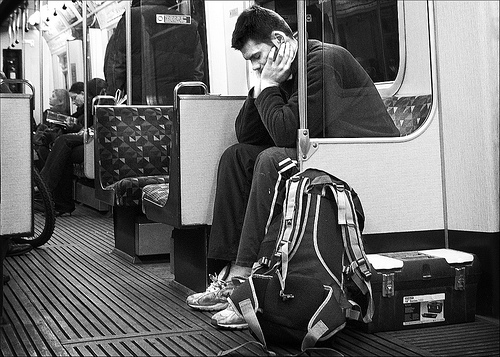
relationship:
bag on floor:
[269, 173, 367, 339] [138, 324, 195, 356]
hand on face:
[264, 44, 290, 79] [248, 40, 270, 76]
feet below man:
[181, 285, 242, 330] [227, 20, 344, 231]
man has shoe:
[227, 20, 344, 231] [184, 272, 254, 323]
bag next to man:
[269, 173, 367, 339] [227, 20, 344, 231]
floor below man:
[138, 324, 195, 356] [227, 20, 344, 231]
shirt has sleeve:
[253, 73, 366, 146] [262, 105, 317, 152]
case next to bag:
[374, 236, 478, 328] [269, 173, 367, 339]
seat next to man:
[111, 96, 188, 205] [227, 20, 344, 231]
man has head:
[227, 20, 344, 231] [204, 10, 291, 83]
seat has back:
[111, 96, 188, 205] [94, 107, 140, 161]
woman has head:
[45, 86, 70, 125] [49, 90, 63, 106]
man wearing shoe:
[227, 20, 344, 231] [184, 272, 254, 323]